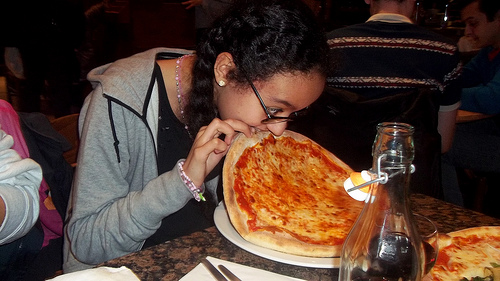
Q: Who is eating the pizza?
A: A girl.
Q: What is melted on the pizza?
A: Cheese.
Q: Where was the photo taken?
A: Restaurant.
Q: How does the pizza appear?
A: Cooked and whole.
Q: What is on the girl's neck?
A: Necklace.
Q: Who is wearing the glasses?
A: Girl.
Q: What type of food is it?
A: Pizza.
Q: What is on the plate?
A: Pizza.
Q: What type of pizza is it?
A: Cheese.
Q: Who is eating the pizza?
A: A girl.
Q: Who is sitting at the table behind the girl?
A: A man.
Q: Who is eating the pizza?
A: The girl at the table.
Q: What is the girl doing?
A: Biting into pizza.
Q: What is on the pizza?
A: Cheese.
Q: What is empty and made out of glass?
A: A bottle.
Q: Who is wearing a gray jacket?
A: A girl.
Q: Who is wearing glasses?
A: A girl.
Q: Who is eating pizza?
A: A girl.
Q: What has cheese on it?
A: The pizza.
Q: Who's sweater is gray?
A: The girl's.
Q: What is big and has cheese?
A: A pizza.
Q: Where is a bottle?
A: On the table.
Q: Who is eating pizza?
A: A girl.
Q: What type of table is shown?
A: Marble.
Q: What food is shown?
A: Pizza.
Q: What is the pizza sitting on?
A: A white plate.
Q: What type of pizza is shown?
A: Cheese.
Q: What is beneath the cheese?
A: Tomato sauce.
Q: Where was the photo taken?
A: At a restaurant.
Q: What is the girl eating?
A: Pizza.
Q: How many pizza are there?
A: Two.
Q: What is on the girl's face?
A: Glasses.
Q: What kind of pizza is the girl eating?
A: Cheese.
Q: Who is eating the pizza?
A: A girl.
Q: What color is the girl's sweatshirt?
A: Grey.